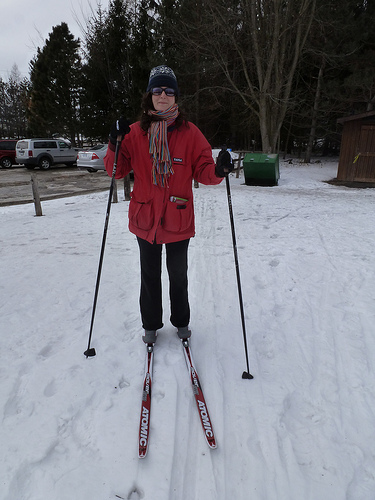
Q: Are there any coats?
A: Yes, there is a coat.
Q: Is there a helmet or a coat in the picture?
A: Yes, there is a coat.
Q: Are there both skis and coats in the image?
A: Yes, there are both a coat and skis.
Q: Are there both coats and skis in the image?
A: Yes, there are both a coat and skis.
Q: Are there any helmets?
A: No, there are no helmets.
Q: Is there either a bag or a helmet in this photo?
A: No, there are no helmets or bags.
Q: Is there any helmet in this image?
A: No, there are no helmets.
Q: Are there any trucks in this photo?
A: No, there are no trucks.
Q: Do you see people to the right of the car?
A: Yes, there is a person to the right of the car.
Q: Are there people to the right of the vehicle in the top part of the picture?
A: Yes, there is a person to the right of the car.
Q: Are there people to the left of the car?
A: No, the person is to the right of the car.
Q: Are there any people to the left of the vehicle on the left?
A: No, the person is to the right of the car.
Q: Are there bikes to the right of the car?
A: No, there is a person to the right of the car.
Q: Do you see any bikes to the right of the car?
A: No, there is a person to the right of the car.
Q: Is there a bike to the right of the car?
A: No, there is a person to the right of the car.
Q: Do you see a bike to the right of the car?
A: No, there is a person to the right of the car.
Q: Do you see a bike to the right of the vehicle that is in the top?
A: No, there is a person to the right of the car.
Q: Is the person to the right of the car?
A: Yes, the person is to the right of the car.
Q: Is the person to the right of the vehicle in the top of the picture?
A: Yes, the person is to the right of the car.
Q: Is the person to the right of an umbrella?
A: No, the person is to the right of the car.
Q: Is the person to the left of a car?
A: No, the person is to the right of a car.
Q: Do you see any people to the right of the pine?
A: Yes, there is a person to the right of the pine.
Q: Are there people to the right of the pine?
A: Yes, there is a person to the right of the pine.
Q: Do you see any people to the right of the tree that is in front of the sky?
A: Yes, there is a person to the right of the pine.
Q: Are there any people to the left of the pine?
A: No, the person is to the right of the pine.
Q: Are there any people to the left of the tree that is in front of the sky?
A: No, the person is to the right of the pine.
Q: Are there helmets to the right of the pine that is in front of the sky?
A: No, there is a person to the right of the pine.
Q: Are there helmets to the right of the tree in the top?
A: No, there is a person to the right of the pine.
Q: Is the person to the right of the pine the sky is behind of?
A: Yes, the person is to the right of the pine tree.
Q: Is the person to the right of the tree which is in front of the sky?
A: Yes, the person is to the right of the pine tree.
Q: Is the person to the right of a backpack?
A: No, the person is to the right of the pine tree.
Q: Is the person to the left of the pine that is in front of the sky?
A: No, the person is to the right of the pine.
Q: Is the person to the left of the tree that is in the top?
A: No, the person is to the right of the pine.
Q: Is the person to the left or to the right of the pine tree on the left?
A: The person is to the right of the pine tree.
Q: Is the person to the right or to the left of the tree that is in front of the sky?
A: The person is to the right of the pine tree.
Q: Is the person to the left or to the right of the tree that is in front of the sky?
A: The person is to the right of the pine tree.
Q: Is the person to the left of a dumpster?
A: Yes, the person is to the left of a dumpster.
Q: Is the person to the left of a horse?
A: No, the person is to the left of a dumpster.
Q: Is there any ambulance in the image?
A: No, there are no ambulances.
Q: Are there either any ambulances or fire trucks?
A: No, there are no ambulances or fire trucks.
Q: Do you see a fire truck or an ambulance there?
A: No, there are no ambulances or fire trucks.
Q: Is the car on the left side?
A: Yes, the car is on the left of the image.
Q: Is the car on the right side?
A: No, the car is on the left of the image.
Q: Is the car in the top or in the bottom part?
A: The car is in the top of the image.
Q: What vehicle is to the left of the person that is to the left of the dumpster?
A: The vehicle is a car.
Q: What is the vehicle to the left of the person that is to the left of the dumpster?
A: The vehicle is a car.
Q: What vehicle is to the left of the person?
A: The vehicle is a car.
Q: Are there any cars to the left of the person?
A: Yes, there is a car to the left of the person.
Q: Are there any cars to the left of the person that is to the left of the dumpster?
A: Yes, there is a car to the left of the person.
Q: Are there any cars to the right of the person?
A: No, the car is to the left of the person.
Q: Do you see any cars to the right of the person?
A: No, the car is to the left of the person.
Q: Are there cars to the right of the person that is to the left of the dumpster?
A: No, the car is to the left of the person.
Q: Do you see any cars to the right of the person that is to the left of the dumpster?
A: No, the car is to the left of the person.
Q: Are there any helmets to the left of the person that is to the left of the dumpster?
A: No, there is a car to the left of the person.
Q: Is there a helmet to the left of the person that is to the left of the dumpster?
A: No, there is a car to the left of the person.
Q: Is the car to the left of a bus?
A: No, the car is to the left of a person.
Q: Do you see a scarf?
A: Yes, there is a scarf.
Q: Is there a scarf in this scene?
A: Yes, there is a scarf.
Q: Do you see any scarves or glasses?
A: Yes, there is a scarf.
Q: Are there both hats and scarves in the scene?
A: Yes, there are both a scarf and a hat.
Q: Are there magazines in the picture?
A: No, there are no magazines.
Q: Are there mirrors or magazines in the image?
A: No, there are no magazines or mirrors.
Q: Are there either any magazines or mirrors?
A: No, there are no magazines or mirrors.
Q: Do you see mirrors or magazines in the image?
A: No, there are no magazines or mirrors.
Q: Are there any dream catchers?
A: No, there are no dream catchers.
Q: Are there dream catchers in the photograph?
A: No, there are no dream catchers.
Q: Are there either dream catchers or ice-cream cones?
A: No, there are no dream catchers or ice-cream cones.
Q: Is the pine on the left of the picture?
A: Yes, the pine is on the left of the image.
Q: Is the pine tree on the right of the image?
A: No, the pine tree is on the left of the image.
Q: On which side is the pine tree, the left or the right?
A: The pine tree is on the left of the image.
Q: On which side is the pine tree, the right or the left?
A: The pine tree is on the left of the image.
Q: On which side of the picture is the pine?
A: The pine is on the left of the image.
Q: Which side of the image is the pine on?
A: The pine is on the left of the image.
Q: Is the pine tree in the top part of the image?
A: Yes, the pine tree is in the top of the image.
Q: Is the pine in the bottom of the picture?
A: No, the pine is in the top of the image.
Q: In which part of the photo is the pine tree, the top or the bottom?
A: The pine tree is in the top of the image.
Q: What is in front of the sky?
A: The pine tree is in front of the sky.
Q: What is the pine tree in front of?
A: The pine tree is in front of the sky.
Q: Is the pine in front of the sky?
A: Yes, the pine is in front of the sky.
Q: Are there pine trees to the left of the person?
A: Yes, there is a pine tree to the left of the person.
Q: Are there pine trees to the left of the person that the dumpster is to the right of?
A: Yes, there is a pine tree to the left of the person.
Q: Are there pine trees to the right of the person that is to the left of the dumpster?
A: No, the pine tree is to the left of the person.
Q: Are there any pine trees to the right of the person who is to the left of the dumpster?
A: No, the pine tree is to the left of the person.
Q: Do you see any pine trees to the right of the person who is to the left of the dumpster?
A: No, the pine tree is to the left of the person.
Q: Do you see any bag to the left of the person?
A: No, there is a pine tree to the left of the person.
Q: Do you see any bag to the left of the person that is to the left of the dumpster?
A: No, there is a pine tree to the left of the person.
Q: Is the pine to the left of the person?
A: Yes, the pine is to the left of the person.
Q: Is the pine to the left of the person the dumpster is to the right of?
A: Yes, the pine is to the left of the person.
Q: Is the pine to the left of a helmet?
A: No, the pine is to the left of the person.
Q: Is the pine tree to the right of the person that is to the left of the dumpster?
A: No, the pine tree is to the left of the person.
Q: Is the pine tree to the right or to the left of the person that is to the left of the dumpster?
A: The pine tree is to the left of the person.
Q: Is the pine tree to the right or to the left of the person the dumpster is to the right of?
A: The pine tree is to the left of the person.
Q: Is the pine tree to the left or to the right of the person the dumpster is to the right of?
A: The pine tree is to the left of the person.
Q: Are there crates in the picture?
A: No, there are no crates.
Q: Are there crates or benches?
A: No, there are no crates or benches.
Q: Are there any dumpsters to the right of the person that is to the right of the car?
A: Yes, there is a dumpster to the right of the person.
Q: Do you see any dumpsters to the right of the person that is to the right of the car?
A: Yes, there is a dumpster to the right of the person.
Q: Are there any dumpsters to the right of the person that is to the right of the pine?
A: Yes, there is a dumpster to the right of the person.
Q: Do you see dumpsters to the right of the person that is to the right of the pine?
A: Yes, there is a dumpster to the right of the person.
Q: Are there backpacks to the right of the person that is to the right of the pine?
A: No, there is a dumpster to the right of the person.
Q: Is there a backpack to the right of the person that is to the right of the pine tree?
A: No, there is a dumpster to the right of the person.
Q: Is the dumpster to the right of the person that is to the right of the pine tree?
A: Yes, the dumpster is to the right of the person.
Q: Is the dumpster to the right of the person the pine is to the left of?
A: Yes, the dumpster is to the right of the person.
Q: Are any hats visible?
A: Yes, there is a hat.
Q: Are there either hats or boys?
A: Yes, there is a hat.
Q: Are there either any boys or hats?
A: Yes, there is a hat.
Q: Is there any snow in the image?
A: Yes, there is snow.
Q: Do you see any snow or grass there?
A: Yes, there is snow.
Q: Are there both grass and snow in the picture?
A: No, there is snow but no grass.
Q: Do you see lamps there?
A: No, there are no lamps.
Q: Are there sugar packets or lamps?
A: No, there are no lamps or sugar packets.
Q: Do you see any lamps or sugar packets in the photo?
A: No, there are no lamps or sugar packets.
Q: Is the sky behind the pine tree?
A: Yes, the sky is behind the pine tree.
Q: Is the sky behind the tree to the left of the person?
A: Yes, the sky is behind the pine tree.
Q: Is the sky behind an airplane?
A: No, the sky is behind the pine tree.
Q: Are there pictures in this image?
A: No, there are no pictures.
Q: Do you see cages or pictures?
A: No, there are no pictures or cages.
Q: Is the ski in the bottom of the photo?
A: Yes, the ski is in the bottom of the image.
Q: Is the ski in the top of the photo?
A: No, the ski is in the bottom of the image.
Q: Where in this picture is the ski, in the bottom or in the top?
A: The ski is in the bottom of the image.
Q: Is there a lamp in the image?
A: No, there are no lamps.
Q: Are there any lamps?
A: No, there are no lamps.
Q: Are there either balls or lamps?
A: No, there are no lamps or balls.